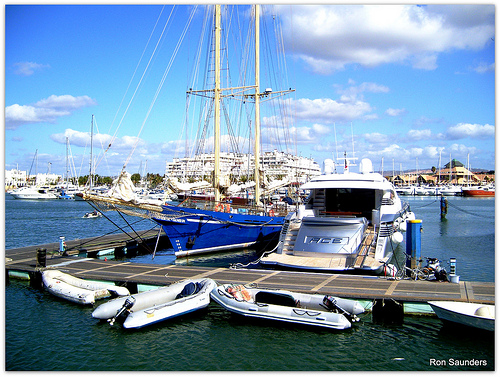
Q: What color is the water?
A: Blue.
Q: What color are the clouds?
A: White.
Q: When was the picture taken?
A: In the daytime.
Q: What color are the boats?
A: Blue and white.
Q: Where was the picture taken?
A: In a harbor.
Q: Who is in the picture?
A: No one.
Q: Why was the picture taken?
A: To show the boats.